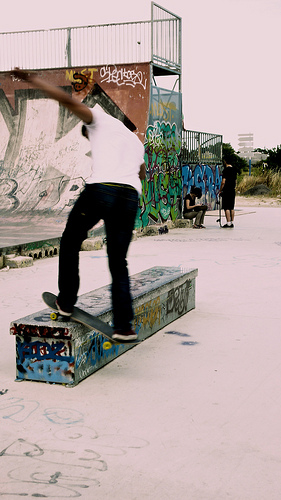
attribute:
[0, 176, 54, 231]
graffiti — white, blue, ledge, mark, wall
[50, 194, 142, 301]
pant — black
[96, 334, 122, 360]
wheel — yellow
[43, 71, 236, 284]
skateboarder — dressed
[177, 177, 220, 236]
person — sitting, skating, skateboarding, trick, use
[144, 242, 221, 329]
ramp — skate, vert, cement, wall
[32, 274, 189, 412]
skateboard — rail, ledge, standing, underneath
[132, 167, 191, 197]
wall — covered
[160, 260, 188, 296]
rail — guard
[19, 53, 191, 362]
man — doing, young, standing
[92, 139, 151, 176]
shirt — white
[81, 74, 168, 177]
boy — young, hold, dressed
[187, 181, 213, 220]
girl — sit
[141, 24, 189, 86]
post — white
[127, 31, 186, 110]
gate — above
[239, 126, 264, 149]
sign — white